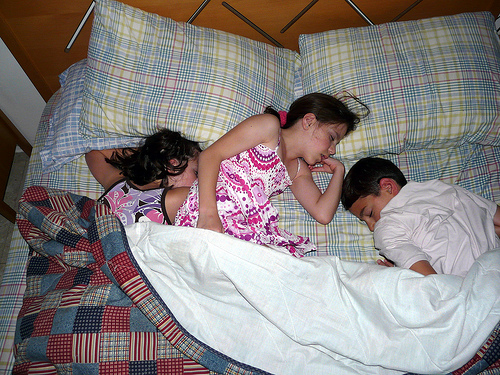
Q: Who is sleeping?
A: The kids.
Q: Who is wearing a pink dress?
A: The girl in the middle.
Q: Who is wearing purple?
A: The girl on the end.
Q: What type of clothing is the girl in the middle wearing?
A: A dress.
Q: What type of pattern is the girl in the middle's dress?
A: Paisley.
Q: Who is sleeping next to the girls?
A: A boy.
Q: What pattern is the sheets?
A: Plaid.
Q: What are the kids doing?
A: Sleeping.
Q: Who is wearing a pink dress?
A: A girl.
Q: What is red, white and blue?
A: The blanket.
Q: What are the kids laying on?
A: Pillows.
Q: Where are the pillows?
A: Under the kids.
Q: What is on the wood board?
A: Silver rods.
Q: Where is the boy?
A: On the right.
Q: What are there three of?
A: Kids.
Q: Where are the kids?
A: On a bed.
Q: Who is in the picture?
A: Children.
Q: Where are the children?
A: In bed.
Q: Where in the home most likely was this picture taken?
A: Bedroom.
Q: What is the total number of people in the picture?
A: 3.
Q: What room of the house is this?
A: Bedroom.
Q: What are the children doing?
A: Sleeping.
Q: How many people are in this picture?
A: 3.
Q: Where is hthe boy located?
A: On the right.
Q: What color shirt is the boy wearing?
A: White.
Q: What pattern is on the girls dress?
A: Paisley.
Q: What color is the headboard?
A: Brown.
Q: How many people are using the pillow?
A: 1.